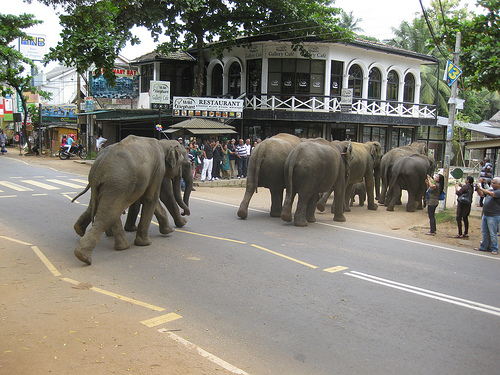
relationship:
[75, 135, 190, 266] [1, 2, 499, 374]
elephant in photo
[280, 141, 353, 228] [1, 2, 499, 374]
elephant in photo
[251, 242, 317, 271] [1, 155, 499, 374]
line on street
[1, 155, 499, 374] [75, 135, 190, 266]
street under elephant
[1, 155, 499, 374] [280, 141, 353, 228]
street under elephant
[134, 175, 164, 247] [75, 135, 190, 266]
leg of elephant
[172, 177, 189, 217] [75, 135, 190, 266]
trunk of elephant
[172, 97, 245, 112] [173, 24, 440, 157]
sign on building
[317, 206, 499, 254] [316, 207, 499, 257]
dirt on ground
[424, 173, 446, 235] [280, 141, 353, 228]
person next to elephant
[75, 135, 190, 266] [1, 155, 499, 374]
elephant in street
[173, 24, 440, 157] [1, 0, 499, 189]
building in background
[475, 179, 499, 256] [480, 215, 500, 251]
person wearing jeans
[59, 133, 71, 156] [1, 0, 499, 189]
woman in background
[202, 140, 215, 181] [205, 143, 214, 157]
man wearing shirt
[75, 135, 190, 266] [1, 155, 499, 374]
elephant crossing street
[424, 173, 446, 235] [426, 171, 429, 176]
person holding phone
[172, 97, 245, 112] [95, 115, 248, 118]
sign on awning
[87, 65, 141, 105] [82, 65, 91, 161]
poster on pole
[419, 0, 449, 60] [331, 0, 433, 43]
lines in sky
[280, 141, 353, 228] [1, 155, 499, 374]
elephant crossing street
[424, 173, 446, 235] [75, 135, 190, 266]
person taking pictures of elephant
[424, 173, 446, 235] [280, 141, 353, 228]
person taking pictures of elephant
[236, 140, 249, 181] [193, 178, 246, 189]
person standing on sidewalk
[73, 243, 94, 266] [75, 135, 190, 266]
foot of elephant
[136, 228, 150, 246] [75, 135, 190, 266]
foot of elephant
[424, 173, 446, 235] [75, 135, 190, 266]
person watching elephant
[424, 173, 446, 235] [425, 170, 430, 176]
person taking picture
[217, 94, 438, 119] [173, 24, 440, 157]
railing on building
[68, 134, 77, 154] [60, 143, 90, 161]
person riding motorcycle